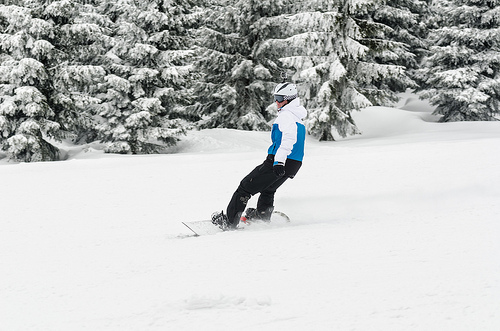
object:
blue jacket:
[254, 95, 316, 163]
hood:
[275, 92, 319, 122]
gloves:
[269, 166, 284, 178]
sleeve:
[273, 110, 299, 164]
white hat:
[268, 73, 298, 96]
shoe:
[210, 212, 235, 229]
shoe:
[247, 205, 272, 222]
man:
[212, 80, 308, 228]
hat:
[269, 78, 300, 105]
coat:
[266, 122, 305, 162]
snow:
[343, 105, 498, 147]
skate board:
[186, 201, 290, 237]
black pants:
[227, 160, 289, 223]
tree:
[398, 0, 498, 125]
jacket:
[256, 99, 312, 166]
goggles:
[272, 93, 295, 102]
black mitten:
[270, 162, 286, 179]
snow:
[2, 119, 496, 329]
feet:
[204, 206, 276, 227]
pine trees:
[350, 0, 457, 120]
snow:
[425, 21, 495, 91]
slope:
[0, 136, 498, 329]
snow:
[287, 15, 411, 93]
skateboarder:
[213, 76, 310, 230]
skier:
[182, 77, 309, 233]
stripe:
[275, 81, 293, 95]